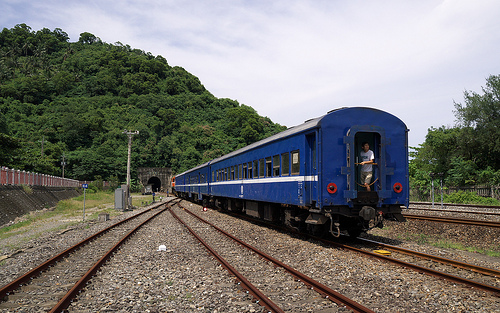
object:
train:
[167, 103, 419, 239]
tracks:
[0, 214, 155, 312]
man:
[357, 140, 376, 191]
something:
[370, 245, 391, 256]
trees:
[0, 20, 38, 60]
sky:
[163, 1, 500, 91]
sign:
[83, 184, 88, 187]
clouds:
[193, 0, 498, 70]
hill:
[0, 14, 173, 196]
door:
[350, 132, 384, 190]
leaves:
[94, 95, 116, 111]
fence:
[415, 183, 499, 207]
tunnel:
[138, 164, 179, 193]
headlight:
[326, 181, 339, 194]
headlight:
[392, 182, 403, 193]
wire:
[120, 125, 140, 138]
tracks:
[168, 195, 375, 312]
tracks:
[370, 231, 498, 307]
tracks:
[363, 208, 499, 233]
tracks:
[399, 199, 499, 220]